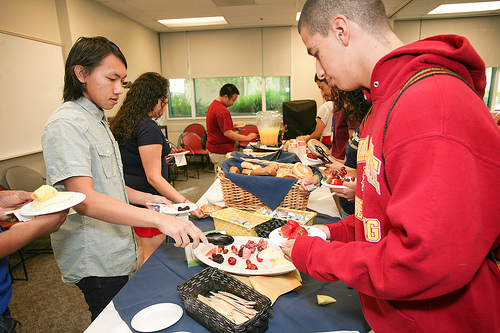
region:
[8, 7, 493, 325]
People are gathering for a party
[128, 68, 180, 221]
Girl wearing black t shirt holding bread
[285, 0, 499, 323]
A guy with red t shirt serving food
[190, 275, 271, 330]
Black Basket full of spoons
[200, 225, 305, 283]
White plate full of sliced fruits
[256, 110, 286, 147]
Juicer contains yellow color fruit juice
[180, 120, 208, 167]
Two red color chairs placed below the window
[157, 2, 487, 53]
Lights are glowing on the roof top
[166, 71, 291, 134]
Besides the window lots of greens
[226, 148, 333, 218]
Basket full of wheat breads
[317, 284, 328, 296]
part of a table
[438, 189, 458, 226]
part of a sweater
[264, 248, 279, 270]
part of a plate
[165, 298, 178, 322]
part of a table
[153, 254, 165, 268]
edge of a table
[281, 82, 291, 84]
part of a window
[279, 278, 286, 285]
part of a cloth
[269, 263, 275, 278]
edge of a plate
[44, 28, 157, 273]
boy with longer hair and greenish shirt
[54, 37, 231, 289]
boy getting fruit with black tongs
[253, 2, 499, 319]
boy with shaved head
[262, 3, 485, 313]
boy in red hoody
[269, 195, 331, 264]
plate of full strawberries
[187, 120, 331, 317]
a buffet table with food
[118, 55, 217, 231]
woman with dark curly hair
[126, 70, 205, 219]
woman in a black shirt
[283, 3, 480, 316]
people getting food from buffett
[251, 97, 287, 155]
a container of orange juice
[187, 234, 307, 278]
Very little fruit left on platter.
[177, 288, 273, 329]
Plastic silverware for convinence.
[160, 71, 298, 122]
Three pane window for viewing.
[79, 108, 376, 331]
Breakfast buffet for sharing event.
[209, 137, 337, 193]
Bagels for type of bread.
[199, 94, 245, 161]
Short sleeve red tee shirt.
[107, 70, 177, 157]
Long brown curly hair brushed out.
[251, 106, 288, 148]
Fresh orange juice for vitamin C.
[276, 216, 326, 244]
Large red luscious strawberries on plate.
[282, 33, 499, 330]
Red sweatshirt with hood and lettering.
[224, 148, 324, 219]
wicker basket full of bread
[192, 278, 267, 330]
wicker basket with plastic utensils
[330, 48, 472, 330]
red hoodie on a man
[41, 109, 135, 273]
light blue short sleeve button down shirt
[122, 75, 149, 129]
long crly hair on a woman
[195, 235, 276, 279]
white plate with fruit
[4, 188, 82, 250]
two hands holding a plate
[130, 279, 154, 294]
blue tablecloth on a table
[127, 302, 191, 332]
empty white circular plate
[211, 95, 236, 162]
red shirt on a man